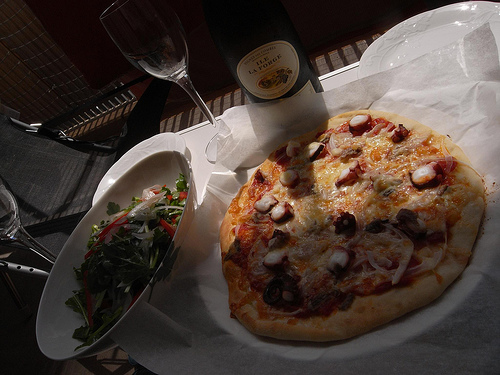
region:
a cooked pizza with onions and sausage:
[212, 105, 493, 352]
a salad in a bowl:
[29, 142, 198, 367]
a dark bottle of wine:
[203, 0, 335, 131]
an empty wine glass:
[94, 2, 244, 161]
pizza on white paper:
[108, 17, 493, 373]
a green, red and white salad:
[60, 162, 194, 349]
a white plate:
[357, 2, 497, 100]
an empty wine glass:
[0, 178, 57, 267]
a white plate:
[85, 121, 190, 210]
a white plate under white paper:
[95, 21, 497, 373]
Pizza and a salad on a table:
[67, 125, 493, 326]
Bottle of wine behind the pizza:
[226, 42, 352, 167]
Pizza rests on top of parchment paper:
[212, 107, 479, 357]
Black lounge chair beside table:
[7, 70, 142, 205]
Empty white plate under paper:
[340, 6, 496, 86]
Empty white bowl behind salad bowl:
[90, 127, 205, 198]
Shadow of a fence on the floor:
[121, 53, 411, 134]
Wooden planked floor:
[148, 65, 361, 120]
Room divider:
[11, 56, 154, 108]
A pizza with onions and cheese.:
[216, 105, 488, 345]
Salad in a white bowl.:
[40, 150, 196, 359]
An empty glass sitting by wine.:
[102, 8, 241, 158]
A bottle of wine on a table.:
[214, 24, 325, 100]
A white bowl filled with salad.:
[33, 147, 199, 357]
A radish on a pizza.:
[408, 161, 438, 186]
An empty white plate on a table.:
[360, 5, 499, 76]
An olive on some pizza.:
[258, 273, 292, 302]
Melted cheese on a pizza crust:
[219, 172, 259, 330]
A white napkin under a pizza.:
[97, 25, 457, 367]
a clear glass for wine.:
[111, 27, 233, 124]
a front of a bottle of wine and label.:
[220, 18, 335, 112]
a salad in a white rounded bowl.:
[62, 185, 205, 339]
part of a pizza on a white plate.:
[212, 145, 498, 276]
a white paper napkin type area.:
[416, 43, 497, 123]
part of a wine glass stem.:
[20, 187, 47, 280]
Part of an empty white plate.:
[345, 25, 487, 94]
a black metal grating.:
[57, 85, 144, 124]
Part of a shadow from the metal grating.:
[324, 30, 391, 57]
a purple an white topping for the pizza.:
[349, 102, 373, 138]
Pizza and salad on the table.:
[43, 110, 459, 349]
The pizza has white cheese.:
[357, 179, 443, 274]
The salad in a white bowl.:
[62, 205, 182, 291]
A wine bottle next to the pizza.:
[193, 28, 328, 129]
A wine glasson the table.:
[102, 16, 237, 151]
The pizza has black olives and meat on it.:
[242, 186, 299, 312]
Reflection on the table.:
[137, 86, 237, 128]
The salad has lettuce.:
[85, 222, 150, 270]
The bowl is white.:
[75, 163, 200, 354]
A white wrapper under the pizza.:
[383, 52, 498, 132]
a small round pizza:
[210, 97, 487, 349]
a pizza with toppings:
[204, 92, 493, 342]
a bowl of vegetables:
[16, 142, 216, 367]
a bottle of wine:
[203, 0, 353, 116]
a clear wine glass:
[89, 4, 245, 169]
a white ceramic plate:
[345, 0, 498, 86]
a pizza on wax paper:
[106, 96, 498, 372]